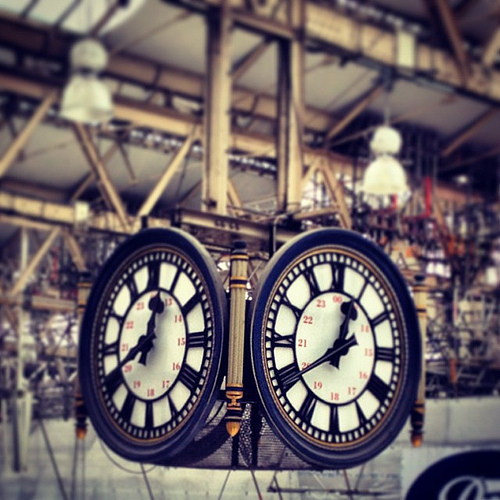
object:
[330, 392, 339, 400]
18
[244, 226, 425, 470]
clock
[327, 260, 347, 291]
number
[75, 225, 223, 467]
clocks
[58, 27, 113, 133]
light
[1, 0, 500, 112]
ceiling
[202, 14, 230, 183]
beam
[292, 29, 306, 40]
bands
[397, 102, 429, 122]
wires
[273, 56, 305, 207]
poles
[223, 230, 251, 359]
pillar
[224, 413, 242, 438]
tip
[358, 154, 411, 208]
shade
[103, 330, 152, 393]
minute hand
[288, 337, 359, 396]
minute hand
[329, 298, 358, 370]
hour hand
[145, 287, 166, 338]
hour hand